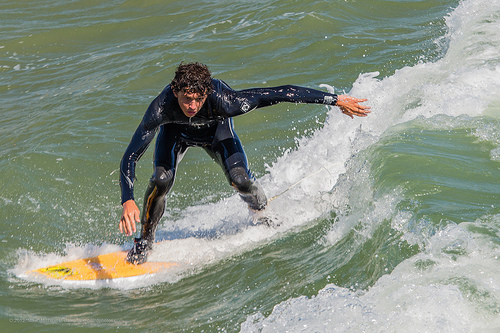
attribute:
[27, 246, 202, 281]
surfboard — yellow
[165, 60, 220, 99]
hair — curly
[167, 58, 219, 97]
hair — wet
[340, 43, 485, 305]
wave — small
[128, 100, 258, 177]
wetsuit — wet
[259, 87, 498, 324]
waves — green and white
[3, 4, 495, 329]
ocean waves — green and white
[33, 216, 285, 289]
surfboard — slim, yellow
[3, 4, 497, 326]
water — green, white, wavy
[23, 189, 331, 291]
surfboard — yellow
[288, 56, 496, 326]
waves — green and white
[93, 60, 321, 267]
wetsuit — black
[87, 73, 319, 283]
wetsuit — black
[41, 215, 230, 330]
surfboard — yellow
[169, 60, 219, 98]
hair — short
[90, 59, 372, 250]
man — wearing